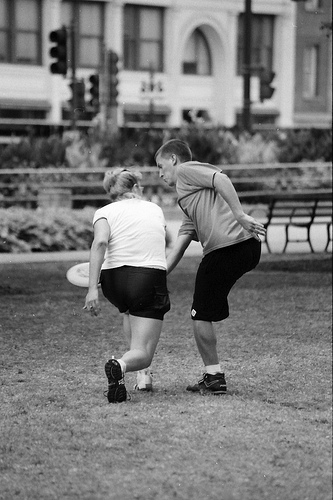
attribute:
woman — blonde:
[87, 163, 173, 404]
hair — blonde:
[100, 166, 145, 200]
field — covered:
[4, 257, 326, 499]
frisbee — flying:
[69, 258, 98, 287]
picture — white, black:
[4, 8, 327, 492]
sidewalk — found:
[174, 221, 332, 250]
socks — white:
[206, 364, 220, 374]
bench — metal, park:
[259, 194, 332, 250]